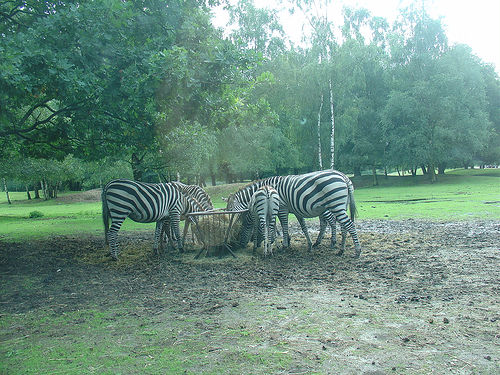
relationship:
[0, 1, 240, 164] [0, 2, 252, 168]
leaves are in tree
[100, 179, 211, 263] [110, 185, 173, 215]
zebra has stripes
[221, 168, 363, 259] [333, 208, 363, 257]
zebra has a back leg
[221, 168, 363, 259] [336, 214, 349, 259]
zebra has a back leg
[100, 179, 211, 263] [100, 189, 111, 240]
zebra has a tail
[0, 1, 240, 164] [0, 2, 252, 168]
leaves are on a tree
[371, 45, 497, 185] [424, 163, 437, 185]
tree has a trunk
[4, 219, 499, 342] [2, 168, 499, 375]
dirt on ground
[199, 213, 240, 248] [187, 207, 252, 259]
hay in a trough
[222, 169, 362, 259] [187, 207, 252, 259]
zebra are eating from a trough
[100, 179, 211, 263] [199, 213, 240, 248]
zebra eating hay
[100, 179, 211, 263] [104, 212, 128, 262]
zebra has hind legs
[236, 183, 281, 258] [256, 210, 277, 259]
zebra has hind legs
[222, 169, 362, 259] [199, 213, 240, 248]
zebra are eating hay